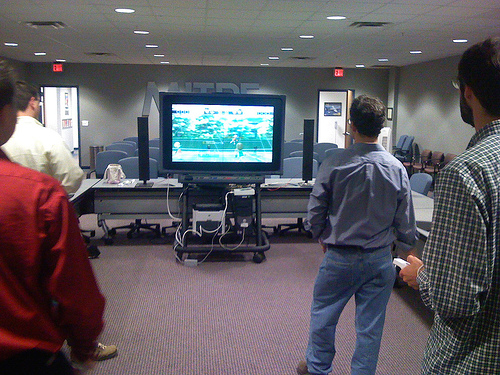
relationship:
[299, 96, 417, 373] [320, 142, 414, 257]
man wearing shirt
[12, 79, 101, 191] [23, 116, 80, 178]
man wearing shirt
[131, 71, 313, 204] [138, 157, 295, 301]
tv set on cart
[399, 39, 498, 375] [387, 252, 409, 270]
man holding wii controller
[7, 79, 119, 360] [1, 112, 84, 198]
man wearing shirt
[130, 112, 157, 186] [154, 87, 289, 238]
speaker surrounding computer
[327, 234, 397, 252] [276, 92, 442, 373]
belt on man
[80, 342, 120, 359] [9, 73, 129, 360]
shoe on man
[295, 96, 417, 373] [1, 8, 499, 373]
man standing in room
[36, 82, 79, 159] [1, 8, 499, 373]
door in room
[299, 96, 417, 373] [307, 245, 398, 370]
man wearing jeans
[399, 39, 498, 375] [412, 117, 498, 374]
man wearing shirt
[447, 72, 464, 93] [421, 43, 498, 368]
glasses are on person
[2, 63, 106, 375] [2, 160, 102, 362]
man wearing red shirt